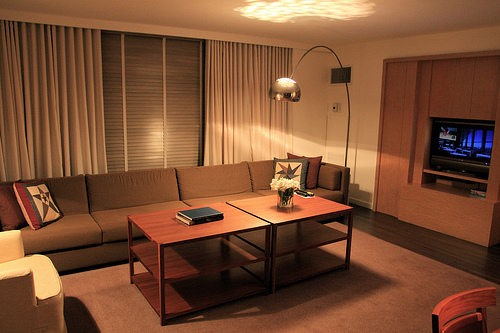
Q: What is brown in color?
A: The table.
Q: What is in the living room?
A: Beige curtains.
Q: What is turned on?
A: The television.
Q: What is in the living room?
A: Lamp.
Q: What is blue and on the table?
A: Book.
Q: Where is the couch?
A: Next to the table.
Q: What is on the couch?
A: Pillows.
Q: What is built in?
A: The television.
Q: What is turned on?
A: The television.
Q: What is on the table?
A: A book.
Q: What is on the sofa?
A: Pillows.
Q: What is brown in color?
A: Sofa.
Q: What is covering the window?
A: Curtains.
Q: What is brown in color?
A: Area rug.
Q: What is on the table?
A: Flowers.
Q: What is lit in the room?
A: Floor lamp.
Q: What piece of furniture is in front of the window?
A: A long tan cough.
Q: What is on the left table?
A: A book.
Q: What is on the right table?
A: Vase with flowers.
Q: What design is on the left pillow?
A: Star.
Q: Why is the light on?
A: It is dark.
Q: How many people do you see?
A: None.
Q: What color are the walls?
A: Off white.